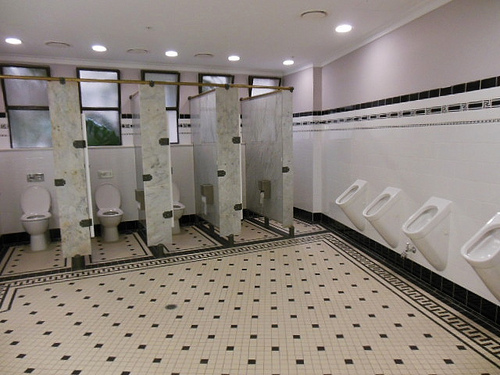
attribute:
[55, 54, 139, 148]
window — glass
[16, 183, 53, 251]
toilet — white, ceramic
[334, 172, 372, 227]
urinal bowl — white, ceramic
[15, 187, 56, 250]
toilet — kemode style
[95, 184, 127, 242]
toilet — kemode style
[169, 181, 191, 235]
toilet — kemode style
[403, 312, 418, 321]
tile — decorative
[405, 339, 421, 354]
tile — decorative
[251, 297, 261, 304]
tile — decorative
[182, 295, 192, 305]
tile — decorative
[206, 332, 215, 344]
tile — decorative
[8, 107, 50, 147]
glass — frosted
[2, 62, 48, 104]
glass — frosted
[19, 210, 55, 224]
toilet seat — plastic, white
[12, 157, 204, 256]
toilets — porcelain, white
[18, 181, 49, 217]
lid — white, plastic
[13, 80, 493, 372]
bathroom — men's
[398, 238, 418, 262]
water line — silver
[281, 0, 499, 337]
wall — white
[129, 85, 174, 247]
stall — gray, marble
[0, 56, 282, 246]
wall — white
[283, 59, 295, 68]
white light — round, glowing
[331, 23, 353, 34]
white light — round, glowing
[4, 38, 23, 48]
white light — round, glowing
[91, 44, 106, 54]
white light — round, glowing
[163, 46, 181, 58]
white light — round, glowing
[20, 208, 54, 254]
bowl — ceramic, white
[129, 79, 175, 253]
marble — gray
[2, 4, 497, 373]
bathroom — public